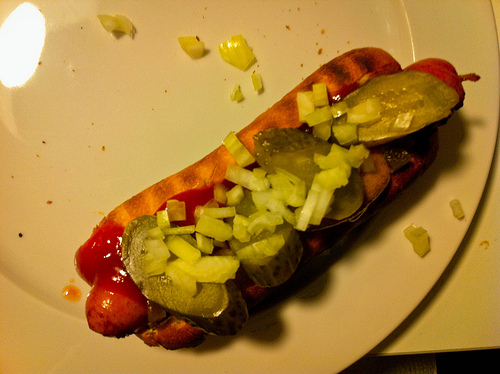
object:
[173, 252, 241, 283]
onion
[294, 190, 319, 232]
onion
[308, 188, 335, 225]
onion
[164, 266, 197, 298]
onion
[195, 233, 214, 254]
onion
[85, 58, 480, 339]
hot dog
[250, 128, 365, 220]
jalepeno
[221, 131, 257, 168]
diced onion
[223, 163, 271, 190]
onion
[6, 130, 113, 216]
brumbs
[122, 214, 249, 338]
jalapeno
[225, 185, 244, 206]
onion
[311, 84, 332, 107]
plaid scarf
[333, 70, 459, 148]
jalepeno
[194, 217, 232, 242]
onion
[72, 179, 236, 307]
ketchup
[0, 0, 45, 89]
light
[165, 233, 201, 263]
onion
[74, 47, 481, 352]
bun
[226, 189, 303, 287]
jalapeno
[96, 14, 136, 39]
onions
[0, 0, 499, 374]
dish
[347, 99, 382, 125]
onions